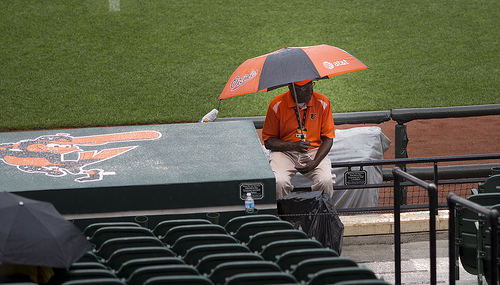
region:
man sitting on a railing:
[210, 30, 375, 217]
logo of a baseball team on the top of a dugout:
[0, 126, 141, 181]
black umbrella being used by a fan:
[2, 183, 121, 278]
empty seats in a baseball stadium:
[93, 215, 349, 282]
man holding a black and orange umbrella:
[206, 39, 368, 209]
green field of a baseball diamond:
[35, 14, 174, 92]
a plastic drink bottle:
[235, 190, 263, 217]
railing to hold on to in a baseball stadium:
[383, 158, 483, 284]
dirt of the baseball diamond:
[431, 128, 485, 152]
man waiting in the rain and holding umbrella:
[194, 38, 356, 201]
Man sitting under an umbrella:
[217, 44, 369, 198]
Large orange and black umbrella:
[216, 43, 368, 141]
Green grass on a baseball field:
[0, 0, 499, 130]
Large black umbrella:
[0, 191, 94, 274]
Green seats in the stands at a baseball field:
[58, 212, 390, 283]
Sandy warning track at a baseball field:
[339, 111, 497, 202]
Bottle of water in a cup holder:
[239, 193, 259, 216]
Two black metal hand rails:
[391, 164, 498, 282]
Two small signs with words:
[236, 167, 368, 202]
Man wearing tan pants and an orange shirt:
[261, 79, 336, 205]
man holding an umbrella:
[211, 26, 378, 214]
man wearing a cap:
[216, 12, 373, 188]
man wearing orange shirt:
[218, 23, 370, 205]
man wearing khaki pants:
[231, 32, 348, 222]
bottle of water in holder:
[240, 172, 261, 222]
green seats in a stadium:
[285, 205, 332, 270]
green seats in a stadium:
[197, 215, 232, 280]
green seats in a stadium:
[126, 222, 164, 274]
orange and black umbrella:
[211, 26, 369, 148]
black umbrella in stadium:
[15, 187, 95, 272]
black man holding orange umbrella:
[217, 39, 371, 229]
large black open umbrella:
[0, 191, 100, 274]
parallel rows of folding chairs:
[41, 209, 391, 283]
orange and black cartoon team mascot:
[0, 122, 158, 189]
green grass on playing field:
[1, 0, 497, 133]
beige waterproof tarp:
[267, 124, 387, 211]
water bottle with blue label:
[242, 191, 257, 214]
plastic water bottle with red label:
[201, 105, 223, 122]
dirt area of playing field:
[337, 114, 499, 214]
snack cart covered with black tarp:
[277, 184, 350, 259]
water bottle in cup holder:
[227, 187, 272, 219]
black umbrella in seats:
[5, 170, 83, 275]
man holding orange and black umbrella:
[211, 41, 368, 241]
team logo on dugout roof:
[5, 67, 202, 184]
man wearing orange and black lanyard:
[201, 34, 371, 211]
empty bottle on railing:
[191, 101, 254, 147]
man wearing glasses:
[208, 41, 355, 197]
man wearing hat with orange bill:
[215, 33, 372, 234]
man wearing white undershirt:
[198, 30, 355, 199]